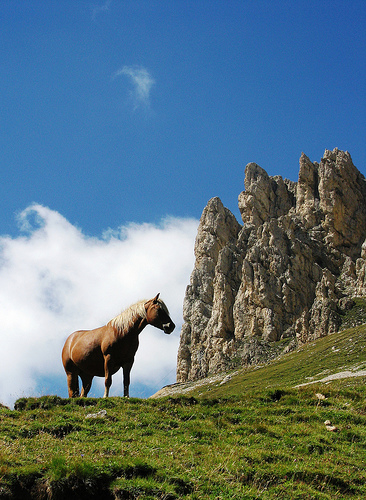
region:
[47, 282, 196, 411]
Horse Standing in an open field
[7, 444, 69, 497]
PAtch of bright green grass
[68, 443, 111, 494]
PAtch of bright green grass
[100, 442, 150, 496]
PAtch of bright green grass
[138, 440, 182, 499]
PAtch of bright green grass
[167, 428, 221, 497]
PAtch of bright green grass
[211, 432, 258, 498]
PAtch of bright green grass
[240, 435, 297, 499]
PAtch of bright green grass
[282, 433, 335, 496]
PAtch of bright green grass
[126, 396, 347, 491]
PAtch of bright green grass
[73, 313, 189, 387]
the horse is in the valley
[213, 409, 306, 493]
the grasses are short in size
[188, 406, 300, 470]
the grasses are green in color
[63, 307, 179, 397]
horse is brown in color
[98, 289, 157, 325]
horse hair is white in color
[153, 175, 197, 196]
the sky is clear blue in color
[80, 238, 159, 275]
sky is coverd by white clouds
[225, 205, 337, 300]
the hill are adjacent to the field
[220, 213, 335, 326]
hills are grey in color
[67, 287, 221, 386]
horse is looking in one direction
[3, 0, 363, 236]
blue of daytime sky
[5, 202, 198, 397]
white cloud in sky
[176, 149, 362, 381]
rock formation on hill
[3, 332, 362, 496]
green grass on hill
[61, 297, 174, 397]
horse standing on hill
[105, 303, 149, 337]
blonde mane on horse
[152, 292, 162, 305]
ear on horse head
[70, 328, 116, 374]
brown coat on torso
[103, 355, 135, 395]
front legs on horse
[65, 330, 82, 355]
light reflection on coat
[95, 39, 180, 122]
small white cloud in sky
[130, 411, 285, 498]
ground covered in green grass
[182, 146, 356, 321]
large grey stone outcropping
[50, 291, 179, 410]
brown horse standing in grassy field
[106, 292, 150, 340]
long blonde hair on back of horse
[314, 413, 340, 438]
small rock laying in grass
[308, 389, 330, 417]
small flower growing in grassy field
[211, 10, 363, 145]
clear blue cloudless sky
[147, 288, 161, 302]
brown ear on horse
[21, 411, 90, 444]
small clump of green grass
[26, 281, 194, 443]
horse standing in the grass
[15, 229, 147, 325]
clouds in the sky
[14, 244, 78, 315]
the clouds are white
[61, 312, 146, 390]
the horse is brown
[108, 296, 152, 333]
horse has blonde mane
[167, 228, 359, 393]
mountain next to the horse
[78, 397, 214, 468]
grass is green and brown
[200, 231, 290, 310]
the mountain is gray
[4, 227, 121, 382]
blue sky with white clouds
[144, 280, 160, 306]
horse has brown ears